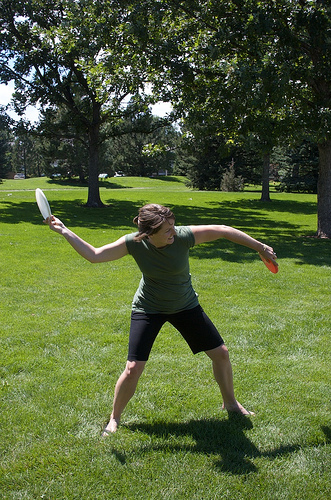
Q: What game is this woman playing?
A: Frisbee golf.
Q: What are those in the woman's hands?
A: Frolfing discs.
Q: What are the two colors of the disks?
A: White and orange.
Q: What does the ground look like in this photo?
A: Plush grass.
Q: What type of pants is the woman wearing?
A: Black bermudas.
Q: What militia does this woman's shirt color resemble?
A: Army.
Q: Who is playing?
A: The woman.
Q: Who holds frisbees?
A: The woman.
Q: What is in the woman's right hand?
A: White frisbee.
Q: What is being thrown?
A: The white frisbee.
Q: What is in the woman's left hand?
A: Orange frisbee.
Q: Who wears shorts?
A: The woman.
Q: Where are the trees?
A: In the park.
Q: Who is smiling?
A: The woman.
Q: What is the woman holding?
A: Frisbee.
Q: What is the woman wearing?
A: Shirt and short.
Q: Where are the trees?
A: At the park.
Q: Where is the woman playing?
A: At the park.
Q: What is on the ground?
A: Shadows and grass.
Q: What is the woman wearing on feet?
A: Flip flops.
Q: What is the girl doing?
A: Playing frisbee.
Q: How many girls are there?
A: One.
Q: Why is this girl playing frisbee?
A: It is fun.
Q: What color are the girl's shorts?
A: Black.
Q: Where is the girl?
A: On the grass.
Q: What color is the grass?
A: Green.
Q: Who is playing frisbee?
A: The girl.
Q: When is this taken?
A: During the day.